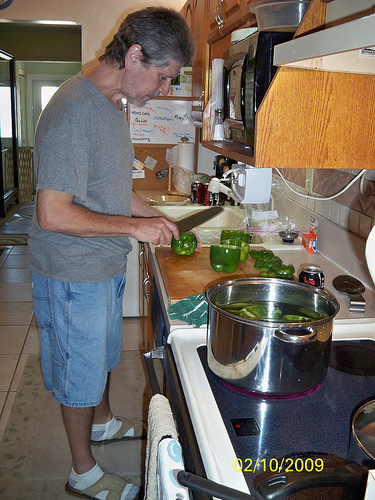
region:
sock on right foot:
[70, 464, 145, 498]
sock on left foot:
[92, 416, 141, 448]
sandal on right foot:
[71, 467, 132, 499]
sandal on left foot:
[95, 413, 139, 439]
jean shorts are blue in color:
[31, 256, 129, 401]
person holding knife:
[153, 186, 210, 257]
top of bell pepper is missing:
[214, 241, 242, 270]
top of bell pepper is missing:
[218, 236, 250, 249]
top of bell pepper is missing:
[223, 220, 253, 237]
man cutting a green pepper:
[163, 205, 218, 258]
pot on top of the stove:
[200, 268, 343, 401]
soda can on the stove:
[293, 265, 329, 286]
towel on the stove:
[140, 389, 188, 498]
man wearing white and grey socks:
[64, 458, 137, 498]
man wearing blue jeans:
[18, 248, 126, 420]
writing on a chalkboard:
[121, 98, 199, 146]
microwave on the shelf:
[212, 42, 266, 145]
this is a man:
[10, 7, 219, 498]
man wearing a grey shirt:
[16, 62, 166, 297]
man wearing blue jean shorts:
[18, 229, 144, 406]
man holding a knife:
[124, 170, 224, 267]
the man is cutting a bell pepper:
[135, 188, 248, 281]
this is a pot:
[178, 266, 355, 412]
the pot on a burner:
[189, 239, 347, 444]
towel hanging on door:
[126, 368, 202, 491]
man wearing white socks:
[64, 450, 128, 499]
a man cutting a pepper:
[43, 42, 220, 445]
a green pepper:
[175, 230, 247, 269]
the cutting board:
[153, 235, 290, 299]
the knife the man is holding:
[173, 193, 219, 239]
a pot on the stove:
[207, 277, 335, 389]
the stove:
[171, 325, 366, 498]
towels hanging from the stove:
[139, 400, 194, 497]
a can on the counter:
[303, 263, 326, 287]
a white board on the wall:
[129, 102, 189, 141]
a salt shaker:
[210, 106, 227, 141]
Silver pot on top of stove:
[205, 273, 337, 398]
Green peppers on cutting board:
[164, 202, 253, 281]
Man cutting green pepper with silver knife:
[149, 205, 225, 256]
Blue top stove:
[258, 399, 347, 454]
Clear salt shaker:
[208, 108, 226, 141]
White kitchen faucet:
[205, 172, 232, 199]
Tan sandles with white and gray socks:
[61, 461, 139, 497]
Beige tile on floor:
[1, 278, 29, 349]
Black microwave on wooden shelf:
[222, 32, 268, 154]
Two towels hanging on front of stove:
[143, 391, 186, 499]